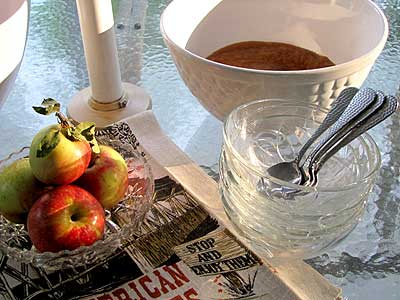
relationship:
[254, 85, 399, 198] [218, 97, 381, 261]
teaspoons in a bowls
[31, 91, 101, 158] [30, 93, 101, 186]
leaves on a apple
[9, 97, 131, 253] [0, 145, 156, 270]
apples in a bowl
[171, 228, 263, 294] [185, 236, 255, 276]
sign has lettering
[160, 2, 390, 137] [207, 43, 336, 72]
bowl with liquid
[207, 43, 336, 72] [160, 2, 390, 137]
liquid in bowl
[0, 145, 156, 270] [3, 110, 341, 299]
bowl on top of newspaper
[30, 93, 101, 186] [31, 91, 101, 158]
apple has leaves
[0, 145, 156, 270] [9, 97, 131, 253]
bowl has apples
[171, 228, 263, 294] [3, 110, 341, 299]
sign on newspaper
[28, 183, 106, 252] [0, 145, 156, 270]
apple in a bowl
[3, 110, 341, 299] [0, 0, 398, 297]
newspaper on table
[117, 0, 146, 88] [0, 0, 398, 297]
reflection on table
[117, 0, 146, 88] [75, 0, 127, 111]
reflection of a pole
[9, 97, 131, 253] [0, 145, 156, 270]
apples are in a bowl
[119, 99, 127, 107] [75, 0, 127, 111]
bolt on pole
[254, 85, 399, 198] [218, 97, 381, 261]
teaspoons are in a bowls